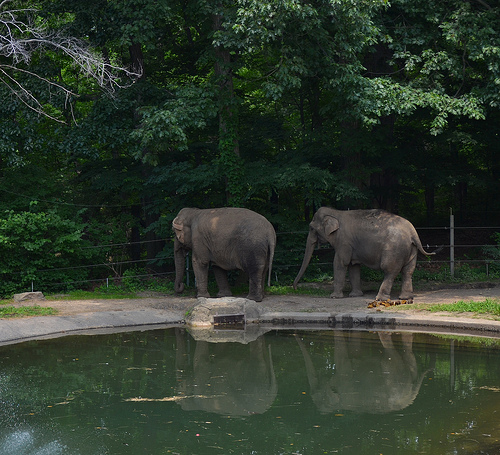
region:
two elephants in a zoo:
[154, 180, 438, 314]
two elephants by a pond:
[162, 188, 446, 325]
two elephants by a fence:
[135, 178, 467, 310]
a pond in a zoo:
[15, 290, 497, 452]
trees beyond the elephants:
[12, 23, 497, 314]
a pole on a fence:
[445, 203, 463, 281]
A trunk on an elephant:
[292, 213, 320, 291]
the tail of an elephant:
[401, 218, 453, 275]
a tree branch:
[8, 8, 136, 133]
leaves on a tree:
[332, 52, 477, 137]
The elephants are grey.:
[158, 201, 425, 301]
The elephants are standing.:
[158, 196, 431, 313]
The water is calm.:
[10, 316, 470, 454]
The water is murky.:
[15, 314, 482, 453]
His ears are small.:
[298, 202, 342, 238]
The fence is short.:
[18, 215, 495, 295]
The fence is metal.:
[3, 226, 498, 283]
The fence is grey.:
[1, 221, 491, 291]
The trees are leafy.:
[0, 6, 492, 211]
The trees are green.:
[15, 51, 497, 219]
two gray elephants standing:
[153, 194, 438, 304]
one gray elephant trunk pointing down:
[291, 233, 316, 289]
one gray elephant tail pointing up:
[411, 229, 437, 259]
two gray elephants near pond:
[111, 195, 490, 452]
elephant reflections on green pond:
[20, 343, 495, 445]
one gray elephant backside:
[238, 207, 280, 269]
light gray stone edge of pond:
[1, 310, 182, 341]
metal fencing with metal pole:
[427, 210, 496, 290]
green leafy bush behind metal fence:
[6, 204, 167, 298]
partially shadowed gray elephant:
[288, 202, 439, 303]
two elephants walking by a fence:
[164, 203, 444, 310]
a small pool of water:
[0, 320, 499, 452]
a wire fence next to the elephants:
[11, 220, 499, 299]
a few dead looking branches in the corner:
[7, 38, 142, 134]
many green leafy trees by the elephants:
[106, 5, 477, 188]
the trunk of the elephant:
[284, 243, 317, 290]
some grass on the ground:
[3, 300, 45, 322]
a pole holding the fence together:
[443, 213, 461, 276]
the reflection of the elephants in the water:
[162, 328, 434, 425]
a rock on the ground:
[8, 285, 50, 304]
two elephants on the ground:
[127, 150, 450, 325]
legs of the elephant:
[322, 248, 423, 310]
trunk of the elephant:
[285, 245, 318, 290]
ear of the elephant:
[317, 213, 347, 245]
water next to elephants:
[246, 332, 325, 405]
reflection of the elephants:
[163, 326, 442, 452]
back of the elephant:
[208, 197, 264, 238]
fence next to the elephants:
[114, 228, 163, 288]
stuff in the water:
[128, 362, 228, 431]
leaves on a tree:
[101, 163, 251, 209]